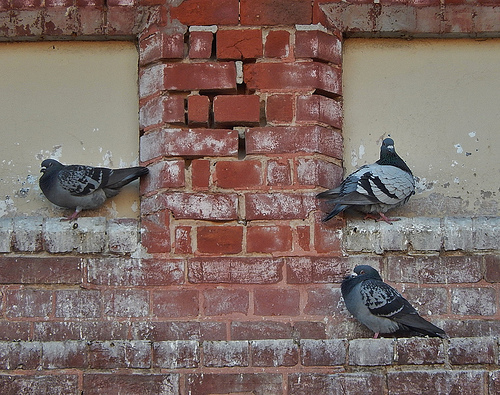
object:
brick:
[261, 26, 291, 56]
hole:
[202, 84, 261, 98]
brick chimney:
[139, 36, 345, 226]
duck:
[341, 264, 448, 338]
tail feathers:
[314, 188, 356, 223]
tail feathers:
[399, 300, 448, 337]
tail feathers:
[107, 165, 146, 190]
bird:
[37, 157, 149, 224]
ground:
[433, 152, 457, 180]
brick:
[215, 28, 262, 60]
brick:
[188, 30, 213, 57]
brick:
[187, 92, 211, 122]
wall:
[138, 28, 343, 256]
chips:
[451, 128, 481, 170]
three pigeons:
[36, 134, 446, 339]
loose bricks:
[181, 25, 260, 153]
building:
[4, 0, 498, 392]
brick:
[210, 157, 269, 189]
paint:
[62, 136, 133, 168]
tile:
[215, 28, 262, 59]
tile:
[166, 61, 239, 90]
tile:
[215, 95, 260, 122]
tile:
[187, 96, 210, 125]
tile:
[160, 130, 239, 156]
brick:
[212, 93, 263, 123]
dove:
[314, 131, 413, 227]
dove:
[339, 263, 444, 340]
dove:
[35, 155, 148, 218]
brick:
[165, 60, 241, 93]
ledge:
[0, 211, 141, 256]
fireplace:
[0, 2, 498, 394]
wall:
[347, 40, 499, 226]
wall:
[0, 40, 138, 225]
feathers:
[356, 169, 411, 205]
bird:
[316, 137, 417, 224]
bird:
[338, 263, 448, 338]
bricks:
[191, 221, 247, 258]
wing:
[347, 163, 415, 209]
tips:
[358, 171, 388, 202]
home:
[7, 3, 489, 393]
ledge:
[346, 217, 496, 261]